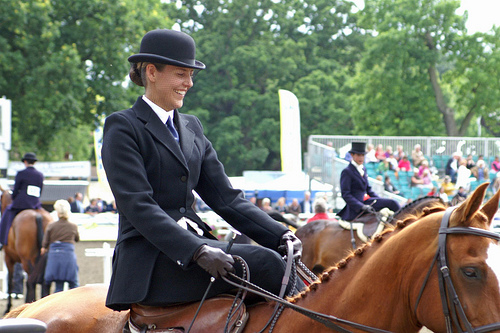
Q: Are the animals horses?
A: Yes, all the animals are horses.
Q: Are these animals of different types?
A: No, all the animals are horses.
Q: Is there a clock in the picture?
A: No, there are no clocks.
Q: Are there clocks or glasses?
A: No, there are no clocks or glasses.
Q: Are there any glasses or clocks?
A: No, there are no clocks or glasses.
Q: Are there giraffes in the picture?
A: No, there are no giraffes.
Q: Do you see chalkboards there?
A: No, there are no chalkboards.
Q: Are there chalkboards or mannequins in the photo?
A: No, there are no chalkboards or mannequins.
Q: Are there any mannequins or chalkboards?
A: No, there are no chalkboards or mannequins.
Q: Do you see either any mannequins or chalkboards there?
A: No, there are no chalkboards or mannequins.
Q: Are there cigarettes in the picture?
A: No, there are no cigarettes.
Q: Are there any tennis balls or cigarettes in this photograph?
A: No, there are no cigarettes or tennis balls.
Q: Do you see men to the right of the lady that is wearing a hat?
A: Yes, there is a man to the right of the lady.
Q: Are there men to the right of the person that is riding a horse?
A: Yes, there is a man to the right of the lady.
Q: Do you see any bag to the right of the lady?
A: No, there is a man to the right of the lady.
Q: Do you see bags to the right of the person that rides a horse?
A: No, there is a man to the right of the lady.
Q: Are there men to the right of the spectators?
A: Yes, there is a man to the right of the spectators.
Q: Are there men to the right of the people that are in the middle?
A: Yes, there is a man to the right of the spectators.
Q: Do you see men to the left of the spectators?
A: No, the man is to the right of the spectators.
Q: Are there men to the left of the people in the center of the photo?
A: No, the man is to the right of the spectators.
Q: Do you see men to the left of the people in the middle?
A: No, the man is to the right of the spectators.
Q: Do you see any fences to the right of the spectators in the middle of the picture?
A: No, there is a man to the right of the spectators.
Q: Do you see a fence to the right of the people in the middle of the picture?
A: No, there is a man to the right of the spectators.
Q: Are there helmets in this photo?
A: No, there are no helmets.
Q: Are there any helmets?
A: No, there are no helmets.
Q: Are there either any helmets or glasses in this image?
A: No, there are no helmets or glasses.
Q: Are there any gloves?
A: Yes, there are gloves.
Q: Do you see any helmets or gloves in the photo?
A: Yes, there are gloves.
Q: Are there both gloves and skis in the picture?
A: No, there are gloves but no skis.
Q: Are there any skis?
A: No, there are no skis.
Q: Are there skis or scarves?
A: No, there are no skis or scarves.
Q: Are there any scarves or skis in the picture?
A: No, there are no skis or scarves.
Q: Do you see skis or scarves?
A: No, there are no skis or scarves.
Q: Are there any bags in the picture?
A: No, there are no bags.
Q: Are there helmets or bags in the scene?
A: No, there are no bags or helmets.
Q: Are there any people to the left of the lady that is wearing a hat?
A: Yes, there is a person to the left of the lady.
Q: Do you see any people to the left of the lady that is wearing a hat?
A: Yes, there is a person to the left of the lady.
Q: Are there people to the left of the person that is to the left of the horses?
A: Yes, there is a person to the left of the lady.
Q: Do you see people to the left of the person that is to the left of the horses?
A: Yes, there is a person to the left of the lady.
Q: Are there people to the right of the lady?
A: No, the person is to the left of the lady.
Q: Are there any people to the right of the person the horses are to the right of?
A: No, the person is to the left of the lady.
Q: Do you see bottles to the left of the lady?
A: No, there is a person to the left of the lady.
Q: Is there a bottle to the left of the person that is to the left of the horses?
A: No, there is a person to the left of the lady.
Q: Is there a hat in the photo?
A: Yes, there is a hat.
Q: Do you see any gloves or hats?
A: Yes, there is a hat.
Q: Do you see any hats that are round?
A: Yes, there is a round hat.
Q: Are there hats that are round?
A: Yes, there is a hat that is round.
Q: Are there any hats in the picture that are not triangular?
A: Yes, there is a round hat.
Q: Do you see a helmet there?
A: No, there are no helmets.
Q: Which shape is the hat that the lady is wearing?
A: The hat is round.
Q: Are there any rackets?
A: No, there are no rackets.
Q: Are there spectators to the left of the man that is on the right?
A: Yes, there are spectators to the left of the man.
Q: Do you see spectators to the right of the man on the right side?
A: No, the spectators are to the left of the man.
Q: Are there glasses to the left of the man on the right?
A: No, there are spectators to the left of the man.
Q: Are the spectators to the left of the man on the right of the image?
A: Yes, the spectators are to the left of the man.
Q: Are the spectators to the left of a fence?
A: No, the spectators are to the left of the man.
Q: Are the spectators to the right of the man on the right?
A: No, the spectators are to the left of the man.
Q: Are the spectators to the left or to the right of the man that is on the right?
A: The spectators are to the left of the man.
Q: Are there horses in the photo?
A: Yes, there is a horse.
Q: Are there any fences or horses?
A: Yes, there is a horse.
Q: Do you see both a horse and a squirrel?
A: No, there is a horse but no squirrels.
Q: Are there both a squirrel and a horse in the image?
A: No, there is a horse but no squirrels.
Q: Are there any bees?
A: No, there are no bees.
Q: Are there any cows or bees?
A: No, there are no bees or cows.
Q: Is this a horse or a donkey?
A: This is a horse.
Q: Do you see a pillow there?
A: No, there are no pillows.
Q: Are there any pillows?
A: No, there are no pillows.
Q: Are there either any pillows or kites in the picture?
A: No, there are no pillows or kites.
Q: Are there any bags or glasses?
A: No, there are no glasses or bags.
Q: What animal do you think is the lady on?
A: The lady is on the horse.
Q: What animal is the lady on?
A: The lady is on the horse.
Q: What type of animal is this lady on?
A: The lady is on the horse.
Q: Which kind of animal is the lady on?
A: The lady is on the horse.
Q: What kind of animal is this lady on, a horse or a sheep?
A: The lady is on a horse.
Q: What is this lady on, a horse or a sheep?
A: The lady is on a horse.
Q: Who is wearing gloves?
A: The lady is wearing gloves.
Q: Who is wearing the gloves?
A: The lady is wearing gloves.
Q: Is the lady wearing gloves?
A: Yes, the lady is wearing gloves.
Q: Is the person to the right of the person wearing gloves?
A: Yes, the lady is wearing gloves.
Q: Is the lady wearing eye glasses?
A: No, the lady is wearing gloves.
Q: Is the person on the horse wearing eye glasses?
A: No, the lady is wearing gloves.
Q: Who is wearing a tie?
A: The lady is wearing a tie.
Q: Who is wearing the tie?
A: The lady is wearing a tie.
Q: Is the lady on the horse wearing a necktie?
A: Yes, the lady is wearing a necktie.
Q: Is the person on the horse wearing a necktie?
A: Yes, the lady is wearing a necktie.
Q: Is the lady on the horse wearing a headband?
A: No, the lady is wearing a necktie.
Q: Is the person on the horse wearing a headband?
A: No, the lady is wearing a necktie.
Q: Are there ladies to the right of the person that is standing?
A: Yes, there is a lady to the right of the person.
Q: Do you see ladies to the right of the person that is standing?
A: Yes, there is a lady to the right of the person.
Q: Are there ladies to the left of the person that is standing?
A: No, the lady is to the right of the person.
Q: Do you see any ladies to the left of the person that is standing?
A: No, the lady is to the right of the person.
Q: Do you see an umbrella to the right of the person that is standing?
A: No, there is a lady to the right of the person.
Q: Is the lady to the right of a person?
A: Yes, the lady is to the right of a person.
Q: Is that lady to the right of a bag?
A: No, the lady is to the right of a person.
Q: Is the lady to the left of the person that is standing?
A: No, the lady is to the right of the person.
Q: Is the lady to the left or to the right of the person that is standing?
A: The lady is to the right of the person.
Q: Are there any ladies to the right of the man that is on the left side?
A: Yes, there is a lady to the right of the man.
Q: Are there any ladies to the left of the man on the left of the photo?
A: No, the lady is to the right of the man.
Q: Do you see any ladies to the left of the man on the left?
A: No, the lady is to the right of the man.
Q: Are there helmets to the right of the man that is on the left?
A: No, there is a lady to the right of the man.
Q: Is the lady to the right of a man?
A: Yes, the lady is to the right of a man.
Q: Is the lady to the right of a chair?
A: No, the lady is to the right of a man.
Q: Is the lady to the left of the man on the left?
A: No, the lady is to the right of the man.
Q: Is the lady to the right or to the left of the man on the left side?
A: The lady is to the right of the man.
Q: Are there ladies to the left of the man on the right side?
A: Yes, there is a lady to the left of the man.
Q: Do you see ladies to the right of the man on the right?
A: No, the lady is to the left of the man.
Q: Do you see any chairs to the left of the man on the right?
A: No, there is a lady to the left of the man.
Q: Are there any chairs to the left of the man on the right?
A: No, there is a lady to the left of the man.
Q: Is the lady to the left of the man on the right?
A: Yes, the lady is to the left of the man.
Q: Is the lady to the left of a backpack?
A: No, the lady is to the left of the man.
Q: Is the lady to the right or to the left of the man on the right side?
A: The lady is to the left of the man.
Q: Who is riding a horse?
A: The lady is riding a horse.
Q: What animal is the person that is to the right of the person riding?
A: The lady is riding a horse.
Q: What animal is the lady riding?
A: The lady is riding a horse.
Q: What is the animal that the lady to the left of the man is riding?
A: The animal is a horse.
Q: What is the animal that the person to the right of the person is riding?
A: The animal is a horse.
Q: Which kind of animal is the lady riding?
A: The lady is riding a horse.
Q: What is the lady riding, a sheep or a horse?
A: The lady is riding a horse.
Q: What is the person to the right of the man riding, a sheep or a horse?
A: The lady is riding a horse.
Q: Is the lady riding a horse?
A: Yes, the lady is riding a horse.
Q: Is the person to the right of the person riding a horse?
A: Yes, the lady is riding a horse.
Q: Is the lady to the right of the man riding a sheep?
A: No, the lady is riding a horse.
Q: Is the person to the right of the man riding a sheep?
A: No, the lady is riding a horse.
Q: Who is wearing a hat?
A: The lady is wearing a hat.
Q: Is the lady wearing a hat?
A: Yes, the lady is wearing a hat.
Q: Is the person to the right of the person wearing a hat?
A: Yes, the lady is wearing a hat.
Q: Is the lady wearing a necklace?
A: No, the lady is wearing a hat.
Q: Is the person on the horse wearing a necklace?
A: No, the lady is wearing a hat.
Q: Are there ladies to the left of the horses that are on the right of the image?
A: Yes, there is a lady to the left of the horses.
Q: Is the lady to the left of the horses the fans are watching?
A: Yes, the lady is to the left of the horses.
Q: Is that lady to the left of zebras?
A: No, the lady is to the left of the horses.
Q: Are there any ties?
A: Yes, there is a tie.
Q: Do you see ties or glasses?
A: Yes, there is a tie.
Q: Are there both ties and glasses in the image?
A: No, there is a tie but no glasses.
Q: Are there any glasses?
A: No, there are no glasses.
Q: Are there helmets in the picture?
A: No, there are no helmets.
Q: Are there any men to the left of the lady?
A: Yes, there is a man to the left of the lady.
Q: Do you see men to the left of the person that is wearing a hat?
A: Yes, there is a man to the left of the lady.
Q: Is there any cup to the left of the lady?
A: No, there is a man to the left of the lady.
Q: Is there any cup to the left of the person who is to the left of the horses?
A: No, there is a man to the left of the lady.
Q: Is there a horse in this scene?
A: Yes, there are horses.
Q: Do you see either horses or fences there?
A: Yes, there are horses.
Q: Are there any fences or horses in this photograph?
A: Yes, there are horses.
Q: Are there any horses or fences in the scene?
A: Yes, there are horses.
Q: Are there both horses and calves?
A: No, there are horses but no calves.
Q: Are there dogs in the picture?
A: No, there are no dogs.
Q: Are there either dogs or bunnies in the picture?
A: No, there are no dogs or bunnies.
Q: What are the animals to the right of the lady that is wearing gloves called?
A: The animals are horses.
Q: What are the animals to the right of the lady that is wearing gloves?
A: The animals are horses.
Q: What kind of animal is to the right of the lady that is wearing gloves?
A: The animals are horses.